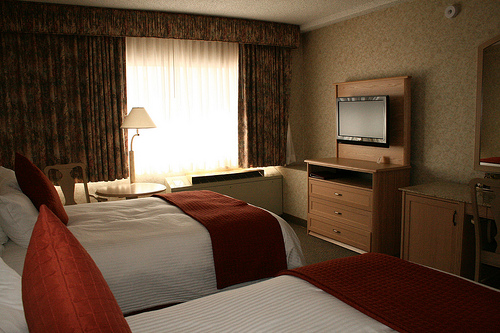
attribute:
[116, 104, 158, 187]
lamp shade — white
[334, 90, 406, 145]
tv — small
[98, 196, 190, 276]
comforter — white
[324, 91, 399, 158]
tv — flat screen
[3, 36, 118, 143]
curtains — dark colored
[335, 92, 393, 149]
television — wall mounted, black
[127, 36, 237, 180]
curtains — sheer, white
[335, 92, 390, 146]
television — mounted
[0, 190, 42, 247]
pillow — white, large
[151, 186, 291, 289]
blanket — long, red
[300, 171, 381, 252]
drawers — wooden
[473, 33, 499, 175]
mirror — wall mirror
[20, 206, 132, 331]
pillow — red, decorative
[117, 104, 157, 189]
lamp — tall